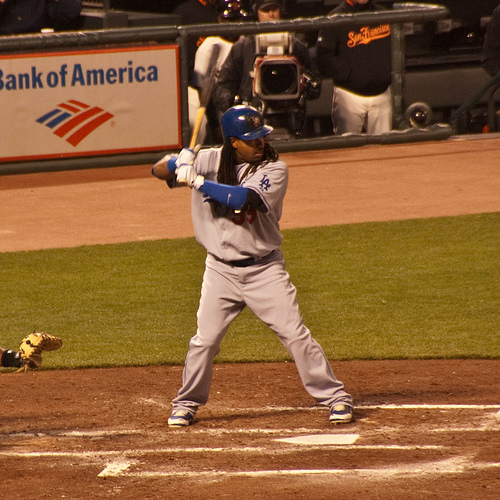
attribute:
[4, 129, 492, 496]
field — baseball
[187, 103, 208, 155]
bat — baseball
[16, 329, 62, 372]
glove — tan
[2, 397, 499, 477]
chalk outline — white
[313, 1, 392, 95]
shirt — black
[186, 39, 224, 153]
bat — black, yellow, wooden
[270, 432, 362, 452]
home plate — flat, white, pentagonal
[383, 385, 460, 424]
chalk — white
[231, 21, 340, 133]
camera — large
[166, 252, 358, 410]
baseball pants — baggy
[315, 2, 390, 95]
jacket — black, orange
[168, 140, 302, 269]
shirt — man's 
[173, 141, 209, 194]
hand — man's 